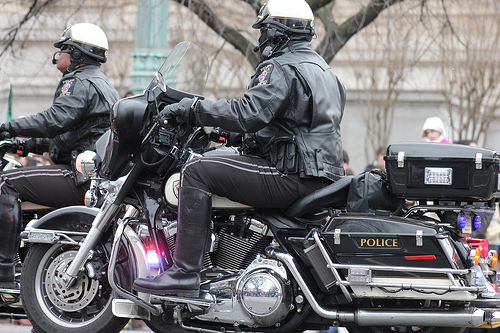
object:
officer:
[130, 0, 346, 299]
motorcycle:
[20, 40, 500, 332]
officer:
[0, 21, 121, 289]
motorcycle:
[0, 131, 55, 316]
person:
[421, 116, 451, 143]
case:
[383, 141, 500, 202]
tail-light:
[467, 237, 489, 259]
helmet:
[251, 0, 316, 53]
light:
[146, 250, 160, 264]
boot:
[131, 186, 213, 298]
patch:
[252, 63, 272, 89]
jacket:
[192, 41, 346, 183]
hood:
[419, 116, 448, 138]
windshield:
[157, 40, 210, 95]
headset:
[251, 37, 271, 53]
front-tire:
[20, 217, 132, 332]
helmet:
[53, 22, 108, 78]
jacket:
[2, 64, 122, 164]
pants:
[178, 154, 348, 210]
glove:
[154, 101, 180, 130]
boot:
[0, 194, 21, 288]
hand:
[0, 122, 16, 140]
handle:
[1, 129, 11, 138]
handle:
[161, 116, 170, 125]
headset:
[52, 50, 82, 64]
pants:
[0, 165, 94, 209]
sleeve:
[190, 64, 291, 134]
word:
[359, 237, 399, 247]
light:
[458, 214, 467, 229]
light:
[473, 214, 481, 231]